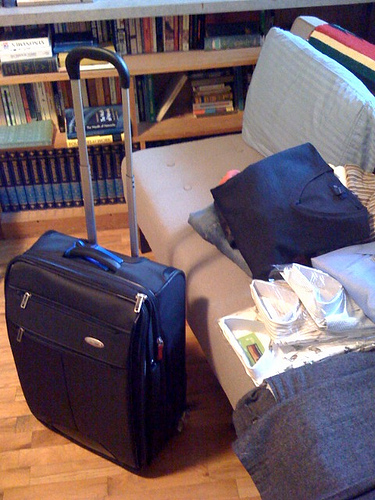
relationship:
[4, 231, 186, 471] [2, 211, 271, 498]
bag in ground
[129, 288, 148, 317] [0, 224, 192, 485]
zip of bag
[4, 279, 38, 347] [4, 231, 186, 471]
zips to bag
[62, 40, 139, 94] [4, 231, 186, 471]
handle on bag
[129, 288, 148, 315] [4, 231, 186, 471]
zip on bag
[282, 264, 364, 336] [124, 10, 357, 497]
shirt on couch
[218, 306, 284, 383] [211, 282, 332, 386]
collar of shirt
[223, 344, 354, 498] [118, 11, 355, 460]
pants on couch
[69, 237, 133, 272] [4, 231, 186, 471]
tag on bag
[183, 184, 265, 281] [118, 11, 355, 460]
pillowcase on couch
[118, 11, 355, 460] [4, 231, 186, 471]
couch by bag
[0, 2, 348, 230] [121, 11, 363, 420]
bookshelf by couch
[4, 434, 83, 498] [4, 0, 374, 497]
flooring of room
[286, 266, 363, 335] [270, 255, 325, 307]
shirt in bag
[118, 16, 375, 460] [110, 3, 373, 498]
couch on right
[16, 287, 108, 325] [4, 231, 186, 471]
zipper of bag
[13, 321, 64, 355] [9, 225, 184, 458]
zipper of luggage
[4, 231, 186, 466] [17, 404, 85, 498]
bag on floor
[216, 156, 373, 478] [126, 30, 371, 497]
clothes on couch